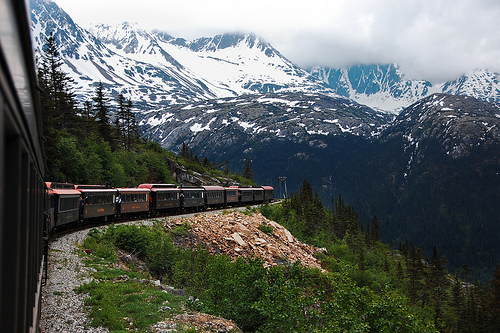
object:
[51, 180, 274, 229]
train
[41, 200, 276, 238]
track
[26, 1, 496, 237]
mountain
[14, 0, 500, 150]
snow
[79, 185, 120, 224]
car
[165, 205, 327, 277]
rocks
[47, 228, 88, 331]
gravels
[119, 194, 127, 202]
window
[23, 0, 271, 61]
peaks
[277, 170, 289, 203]
structure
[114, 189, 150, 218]
cars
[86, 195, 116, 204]
windows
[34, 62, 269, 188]
trees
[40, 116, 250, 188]
bushes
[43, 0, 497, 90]
cloud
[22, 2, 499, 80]
sky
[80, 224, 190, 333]
grass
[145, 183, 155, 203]
corner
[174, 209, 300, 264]
woodchips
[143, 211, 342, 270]
ground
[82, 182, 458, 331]
plants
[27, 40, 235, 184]
forest